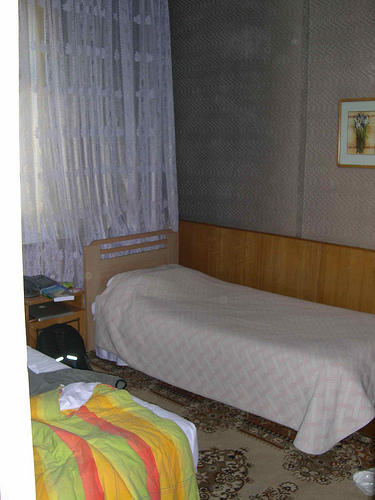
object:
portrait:
[335, 98, 375, 167]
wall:
[152, 0, 373, 312]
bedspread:
[30, 382, 199, 498]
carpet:
[74, 349, 374, 500]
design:
[195, 445, 254, 497]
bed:
[81, 225, 374, 456]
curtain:
[21, 2, 181, 291]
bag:
[34, 323, 93, 371]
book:
[41, 282, 76, 303]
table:
[22, 288, 91, 360]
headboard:
[80, 228, 181, 353]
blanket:
[28, 367, 128, 398]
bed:
[26, 338, 199, 499]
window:
[29, 2, 149, 227]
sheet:
[28, 380, 201, 500]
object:
[352, 469, 374, 499]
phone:
[23, 274, 60, 297]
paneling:
[175, 217, 372, 316]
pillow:
[106, 264, 186, 297]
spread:
[94, 265, 373, 454]